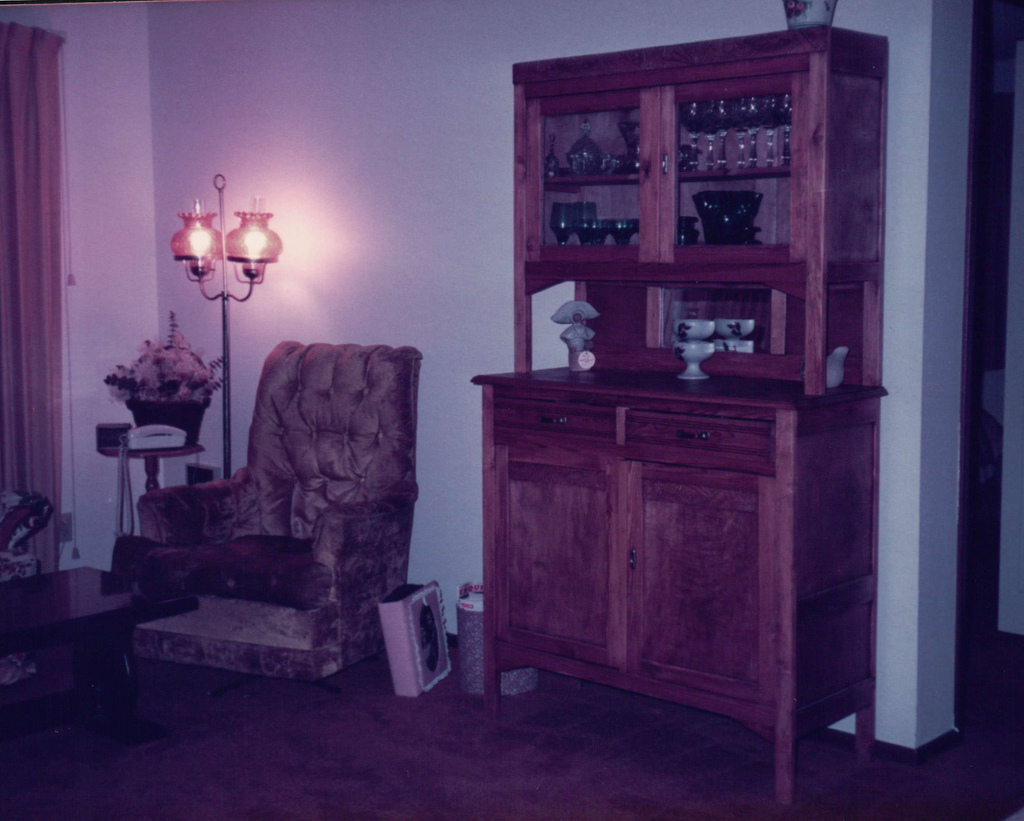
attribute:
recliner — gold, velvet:
[127, 317, 404, 679]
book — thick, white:
[373, 582, 475, 703]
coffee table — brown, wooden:
[25, 547, 204, 760]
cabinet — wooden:
[533, 104, 857, 377]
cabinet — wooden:
[515, 176, 629, 268]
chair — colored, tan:
[138, 365, 401, 613]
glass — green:
[515, 176, 668, 290]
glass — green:
[559, 207, 605, 249]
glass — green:
[546, 185, 686, 285]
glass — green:
[597, 197, 712, 280]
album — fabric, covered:
[332, 567, 501, 688]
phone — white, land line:
[103, 412, 209, 477]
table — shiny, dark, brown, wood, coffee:
[15, 565, 221, 718]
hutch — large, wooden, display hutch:
[454, 58, 835, 688]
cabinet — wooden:
[468, 12, 894, 812]